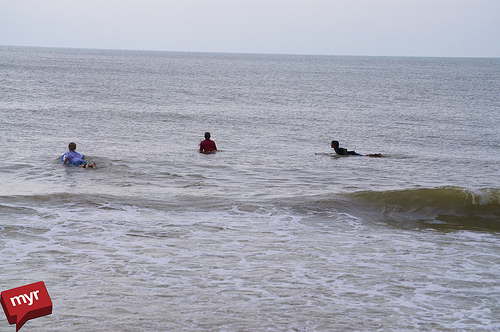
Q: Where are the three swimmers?
A: In water.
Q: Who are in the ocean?
A: Three boys.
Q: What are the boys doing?
A: Swimming.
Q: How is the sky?
A: Blue and clear.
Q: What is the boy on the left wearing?
A: Blue swimsuit.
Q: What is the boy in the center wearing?
A: Red swimsuit.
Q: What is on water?
A: White foam.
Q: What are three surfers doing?
A: Paddling to catch waves.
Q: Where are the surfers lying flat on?
A: Surf board.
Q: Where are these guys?
A: In the ocean.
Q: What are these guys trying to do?
A: Surfing.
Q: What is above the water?
A: The skyline.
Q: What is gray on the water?
A: A wave.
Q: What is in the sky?
A: Clouds.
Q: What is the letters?
A: Myr.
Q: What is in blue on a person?
A: Shirt.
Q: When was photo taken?
A: Daytime.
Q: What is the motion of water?
A: Waves.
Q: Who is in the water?
A: Three people.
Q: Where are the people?
A: Beach.